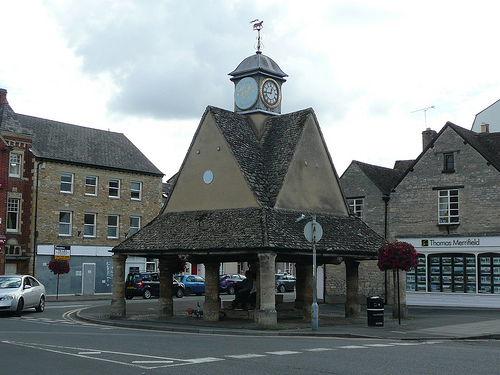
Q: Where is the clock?
A: On the structure.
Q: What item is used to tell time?
A: A clock.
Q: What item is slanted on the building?
A: A roof.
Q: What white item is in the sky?
A: A cloud.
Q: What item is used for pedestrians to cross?
A: A cross walk.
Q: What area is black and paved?
A: A road.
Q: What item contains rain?
A: A cloud.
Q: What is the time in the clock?
A: 12:45 p.m.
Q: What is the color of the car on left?
A: Silver.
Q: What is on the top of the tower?
A: A clock.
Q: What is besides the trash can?
A: A hanging flower basket.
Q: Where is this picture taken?
A: On a street.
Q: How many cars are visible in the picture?
A: Five.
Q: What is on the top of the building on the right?
A: Antenna.